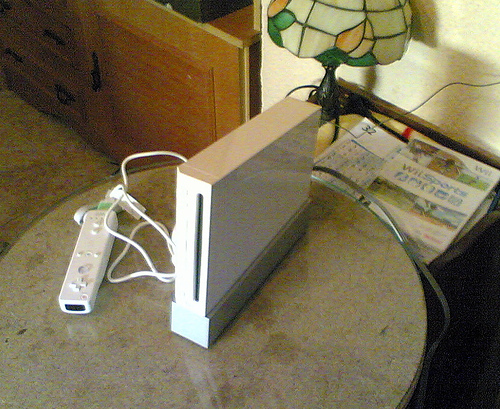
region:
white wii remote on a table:
[54, 208, 117, 315]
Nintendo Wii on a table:
[167, 94, 323, 350]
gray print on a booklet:
[398, 158, 425, 177]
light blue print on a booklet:
[420, 173, 472, 199]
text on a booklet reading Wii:
[398, 161, 425, 179]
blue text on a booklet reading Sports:
[423, 171, 469, 198]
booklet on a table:
[353, 128, 498, 265]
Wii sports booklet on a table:
[354, 134, 496, 264]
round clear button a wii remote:
[75, 263, 92, 275]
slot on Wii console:
[191, 191, 206, 311]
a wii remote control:
[54, 203, 116, 313]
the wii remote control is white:
[63, 205, 113, 317]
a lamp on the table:
[266, 0, 416, 130]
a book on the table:
[371, 123, 499, 253]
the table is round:
[0, 170, 434, 406]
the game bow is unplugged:
[166, 99, 325, 344]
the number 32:
[360, 121, 380, 135]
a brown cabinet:
[6, 1, 267, 173]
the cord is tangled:
[103, 148, 185, 287]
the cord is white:
[108, 145, 180, 291]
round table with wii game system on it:
[1, 161, 431, 407]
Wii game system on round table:
[56, 95, 325, 350]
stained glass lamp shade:
[262, 1, 415, 68]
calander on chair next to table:
[310, 116, 497, 266]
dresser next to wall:
[1, 1, 257, 165]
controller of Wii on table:
[56, 206, 121, 315]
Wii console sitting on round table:
[168, 95, 324, 345]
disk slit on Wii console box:
[193, 192, 201, 304]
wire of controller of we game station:
[106, 141, 174, 287]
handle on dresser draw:
[51, 82, 74, 107]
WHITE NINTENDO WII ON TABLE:
[165, 127, 325, 364]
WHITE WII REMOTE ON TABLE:
[45, 172, 136, 291]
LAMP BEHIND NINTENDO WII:
[272, 12, 409, 92]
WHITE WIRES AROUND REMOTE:
[127, 155, 172, 276]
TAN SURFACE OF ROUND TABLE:
[2, 155, 411, 369]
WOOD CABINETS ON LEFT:
[16, 11, 191, 133]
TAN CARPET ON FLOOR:
[1, 109, 84, 193]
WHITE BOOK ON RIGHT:
[369, 123, 497, 243]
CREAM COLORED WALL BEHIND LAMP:
[433, 9, 491, 66]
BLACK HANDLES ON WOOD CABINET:
[84, 48, 111, 112]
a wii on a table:
[69, 51, 457, 395]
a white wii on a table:
[83, 113, 410, 398]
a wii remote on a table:
[54, 195, 153, 321]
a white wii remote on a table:
[57, 186, 154, 333]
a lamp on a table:
[235, 18, 446, 180]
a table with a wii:
[3, 83, 489, 407]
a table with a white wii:
[22, 30, 409, 407]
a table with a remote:
[17, 118, 303, 403]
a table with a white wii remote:
[29, 136, 327, 384]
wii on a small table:
[119, 143, 492, 401]